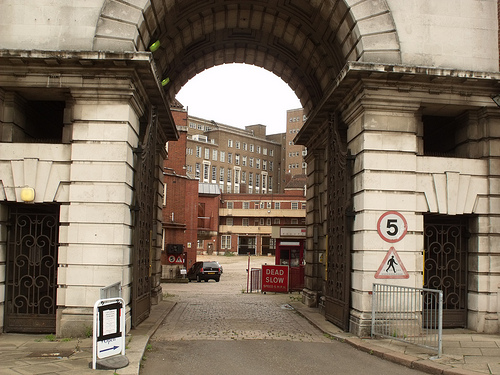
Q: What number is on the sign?
A: 5.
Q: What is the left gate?
A: The gate is brown.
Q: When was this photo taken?
A: In the daytime.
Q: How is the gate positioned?
A: The gate is open.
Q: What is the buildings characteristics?
A: A large light tan brick building with white trim.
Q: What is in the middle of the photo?
A: An arch.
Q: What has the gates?
A: A stone archway with gates.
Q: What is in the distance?
A: Buildings in the distance.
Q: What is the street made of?
A: Bricks.